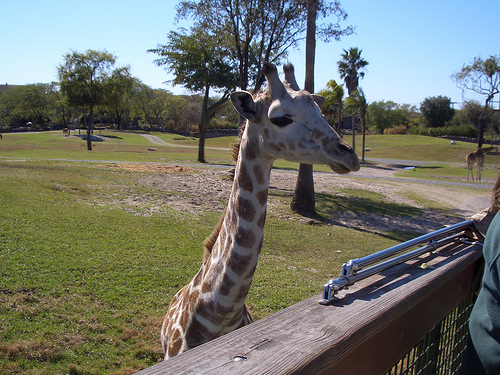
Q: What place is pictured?
A: It is a park.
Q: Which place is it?
A: It is a park.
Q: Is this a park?
A: Yes, it is a park.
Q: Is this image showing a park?
A: Yes, it is showing a park.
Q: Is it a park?
A: Yes, it is a park.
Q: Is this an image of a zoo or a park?
A: It is showing a park.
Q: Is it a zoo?
A: No, it is a park.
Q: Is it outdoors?
A: Yes, it is outdoors.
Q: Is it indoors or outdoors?
A: It is outdoors.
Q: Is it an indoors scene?
A: No, it is outdoors.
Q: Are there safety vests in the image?
A: No, there are no safety vests.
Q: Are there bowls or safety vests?
A: No, there are no safety vests or bowls.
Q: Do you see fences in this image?
A: Yes, there is a fence.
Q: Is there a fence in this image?
A: Yes, there is a fence.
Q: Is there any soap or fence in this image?
A: Yes, there is a fence.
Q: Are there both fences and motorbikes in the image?
A: No, there is a fence but no motorcycles.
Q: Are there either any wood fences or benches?
A: Yes, there is a wood fence.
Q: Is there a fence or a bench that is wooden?
A: Yes, the fence is wooden.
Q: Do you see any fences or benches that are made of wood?
A: Yes, the fence is made of wood.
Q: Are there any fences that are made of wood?
A: Yes, there is a fence that is made of wood.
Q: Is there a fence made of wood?
A: Yes, there is a fence that is made of wood.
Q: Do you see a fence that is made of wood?
A: Yes, there is a fence that is made of wood.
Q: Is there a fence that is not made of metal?
A: Yes, there is a fence that is made of wood.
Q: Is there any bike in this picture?
A: No, there are no bikes.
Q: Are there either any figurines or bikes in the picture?
A: No, there are no bikes or figurines.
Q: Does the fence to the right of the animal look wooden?
A: Yes, the fence is wooden.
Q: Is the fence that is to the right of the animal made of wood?
A: Yes, the fence is made of wood.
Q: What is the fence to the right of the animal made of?
A: The fence is made of wood.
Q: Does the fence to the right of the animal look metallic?
A: No, the fence is wooden.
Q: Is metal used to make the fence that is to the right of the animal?
A: No, the fence is made of wood.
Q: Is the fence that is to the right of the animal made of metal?
A: No, the fence is made of wood.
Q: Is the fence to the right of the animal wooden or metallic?
A: The fence is wooden.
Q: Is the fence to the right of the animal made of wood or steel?
A: The fence is made of wood.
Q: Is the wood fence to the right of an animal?
A: Yes, the fence is to the right of an animal.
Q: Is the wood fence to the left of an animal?
A: No, the fence is to the right of an animal.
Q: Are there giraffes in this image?
A: Yes, there is a giraffe.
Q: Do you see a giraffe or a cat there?
A: Yes, there is a giraffe.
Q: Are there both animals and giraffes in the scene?
A: Yes, there are both a giraffe and animals.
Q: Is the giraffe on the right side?
A: Yes, the giraffe is on the right of the image.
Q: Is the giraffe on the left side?
A: No, the giraffe is on the right of the image.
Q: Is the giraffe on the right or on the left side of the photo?
A: The giraffe is on the right of the image.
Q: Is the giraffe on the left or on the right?
A: The giraffe is on the right of the image.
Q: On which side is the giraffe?
A: The giraffe is on the right of the image.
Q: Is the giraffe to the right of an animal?
A: Yes, the giraffe is to the right of an animal.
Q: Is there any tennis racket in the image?
A: No, there are no rackets.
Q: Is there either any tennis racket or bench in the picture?
A: No, there are no rackets or benches.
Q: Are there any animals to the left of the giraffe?
A: Yes, there is an animal to the left of the giraffe.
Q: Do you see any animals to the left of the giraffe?
A: Yes, there is an animal to the left of the giraffe.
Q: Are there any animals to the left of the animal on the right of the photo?
A: Yes, there is an animal to the left of the giraffe.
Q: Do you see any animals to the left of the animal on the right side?
A: Yes, there is an animal to the left of the giraffe.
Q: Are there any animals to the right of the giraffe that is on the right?
A: No, the animal is to the left of the giraffe.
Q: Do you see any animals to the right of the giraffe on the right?
A: No, the animal is to the left of the giraffe.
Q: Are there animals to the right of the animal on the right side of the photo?
A: No, the animal is to the left of the giraffe.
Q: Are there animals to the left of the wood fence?
A: Yes, there is an animal to the left of the fence.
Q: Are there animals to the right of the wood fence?
A: No, the animal is to the left of the fence.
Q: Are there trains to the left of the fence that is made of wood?
A: No, there is an animal to the left of the fence.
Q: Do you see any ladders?
A: No, there are no ladders.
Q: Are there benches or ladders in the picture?
A: No, there are no ladders or benches.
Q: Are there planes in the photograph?
A: No, there are no planes.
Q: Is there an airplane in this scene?
A: No, there are no airplanes.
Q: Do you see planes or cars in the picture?
A: No, there are no planes or cars.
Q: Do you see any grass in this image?
A: Yes, there is grass.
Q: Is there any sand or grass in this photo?
A: Yes, there is grass.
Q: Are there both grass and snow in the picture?
A: No, there is grass but no snow.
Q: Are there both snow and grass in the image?
A: No, there is grass but no snow.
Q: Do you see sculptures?
A: No, there are no sculptures.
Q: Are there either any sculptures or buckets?
A: No, there are no sculptures or buckets.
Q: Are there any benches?
A: No, there are no benches.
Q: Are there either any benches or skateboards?
A: No, there are no benches or skateboards.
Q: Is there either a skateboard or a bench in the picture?
A: No, there are no benches or skateboards.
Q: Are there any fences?
A: Yes, there is a fence.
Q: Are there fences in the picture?
A: Yes, there is a fence.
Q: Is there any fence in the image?
A: Yes, there is a fence.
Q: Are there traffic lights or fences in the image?
A: Yes, there is a fence.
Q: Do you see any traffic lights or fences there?
A: Yes, there is a fence.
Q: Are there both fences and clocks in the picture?
A: No, there is a fence but no clocks.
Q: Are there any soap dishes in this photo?
A: No, there are no soap dishes.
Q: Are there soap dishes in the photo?
A: No, there are no soap dishes.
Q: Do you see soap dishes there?
A: No, there are no soap dishes.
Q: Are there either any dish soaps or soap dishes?
A: No, there are no soap dishes or dish soaps.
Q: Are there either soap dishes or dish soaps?
A: No, there are no soap dishes or dish soaps.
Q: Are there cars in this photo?
A: No, there are no cars.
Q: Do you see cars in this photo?
A: No, there are no cars.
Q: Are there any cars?
A: No, there are no cars.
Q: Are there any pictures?
A: No, there are no pictures.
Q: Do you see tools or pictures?
A: No, there are no pictures or tools.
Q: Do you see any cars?
A: No, there are no cars.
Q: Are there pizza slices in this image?
A: No, there are no pizza slices.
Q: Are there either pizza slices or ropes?
A: No, there are no pizza slices or ropes.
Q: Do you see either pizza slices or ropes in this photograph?
A: No, there are no pizza slices or ropes.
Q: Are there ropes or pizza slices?
A: No, there are no pizza slices or ropes.